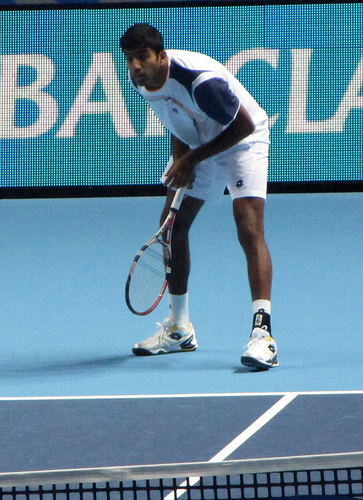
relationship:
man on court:
[122, 23, 298, 311] [34, 229, 94, 330]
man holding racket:
[122, 23, 298, 311] [111, 192, 194, 337]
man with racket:
[122, 23, 298, 311] [111, 192, 194, 337]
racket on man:
[111, 192, 194, 337] [122, 23, 298, 311]